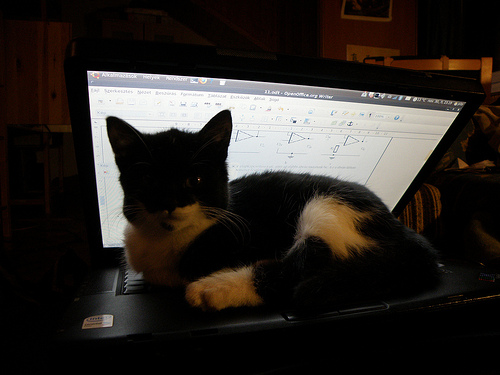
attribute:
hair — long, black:
[209, 165, 426, 300]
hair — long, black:
[241, 180, 443, 292]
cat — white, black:
[101, 110, 448, 317]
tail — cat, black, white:
[297, 228, 443, 314]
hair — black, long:
[157, 134, 203, 162]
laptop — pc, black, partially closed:
[80, 39, 482, 316]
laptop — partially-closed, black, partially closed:
[57, 40, 498, 351]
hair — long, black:
[296, 174, 422, 285]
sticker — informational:
[80, 312, 115, 331]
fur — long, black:
[107, 110, 437, 303]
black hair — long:
[232, 212, 287, 252]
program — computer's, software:
[89, 65, 468, 244]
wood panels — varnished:
[0, 2, 70, 132]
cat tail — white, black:
[287, 208, 441, 304]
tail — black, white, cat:
[270, 215, 453, 324]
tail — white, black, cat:
[266, 250, 368, 311]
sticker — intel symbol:
[81, 305, 118, 330]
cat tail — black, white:
[289, 200, 439, 319]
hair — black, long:
[300, 167, 313, 184]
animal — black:
[100, 107, 443, 318]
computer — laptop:
[53, 42, 498, 347]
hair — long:
[247, 178, 280, 218]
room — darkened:
[6, 8, 484, 346]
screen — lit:
[83, 63, 465, 244]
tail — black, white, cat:
[299, 218, 442, 298]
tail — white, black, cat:
[277, 237, 440, 305]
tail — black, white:
[259, 222, 456, 309]